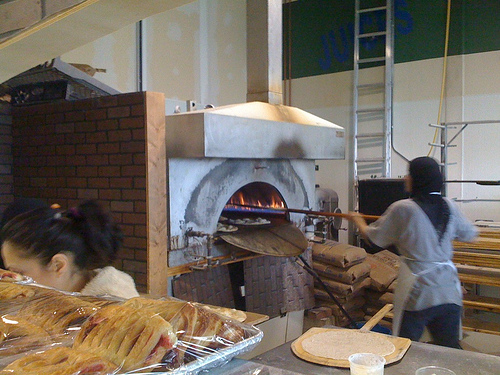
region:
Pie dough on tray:
[297, 321, 409, 368]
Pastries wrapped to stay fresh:
[4, 275, 260, 372]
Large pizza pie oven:
[153, 92, 339, 282]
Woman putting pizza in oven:
[342, 151, 483, 343]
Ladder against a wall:
[345, 4, 400, 245]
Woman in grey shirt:
[342, 152, 489, 352]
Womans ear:
[46, 250, 78, 279]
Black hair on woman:
[402, 157, 463, 239]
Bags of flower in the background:
[315, 238, 390, 318]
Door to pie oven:
[220, 221, 317, 261]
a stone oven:
[119, 78, 418, 308]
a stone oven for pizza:
[137, 77, 428, 327]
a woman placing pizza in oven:
[189, 45, 496, 279]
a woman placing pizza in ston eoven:
[125, 67, 497, 352]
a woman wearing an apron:
[325, 135, 499, 310]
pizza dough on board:
[285, 298, 436, 373]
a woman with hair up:
[4, 167, 141, 299]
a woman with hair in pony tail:
[4, 186, 154, 310]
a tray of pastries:
[7, 227, 273, 372]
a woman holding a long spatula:
[224, 139, 499, 269]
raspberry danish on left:
[83, 305, 161, 374]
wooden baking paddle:
[312, 310, 390, 372]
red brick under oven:
[252, 257, 309, 308]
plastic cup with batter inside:
[347, 347, 382, 374]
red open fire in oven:
[231, 188, 291, 231]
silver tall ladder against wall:
[355, 72, 405, 136]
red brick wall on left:
[89, 110, 166, 192]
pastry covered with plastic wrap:
[10, 318, 83, 359]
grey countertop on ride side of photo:
[431, 346, 488, 372]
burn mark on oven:
[274, 96, 309, 158]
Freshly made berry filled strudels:
[0, 261, 267, 371]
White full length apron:
[385, 250, 471, 345]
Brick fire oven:
[165, 120, 330, 246]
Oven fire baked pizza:
[227, 210, 273, 227]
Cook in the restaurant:
[372, 140, 479, 330]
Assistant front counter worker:
[1, 195, 157, 313]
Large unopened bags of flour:
[313, 226, 408, 321]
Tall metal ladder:
[340, 1, 395, 252]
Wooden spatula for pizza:
[281, 281, 422, 371]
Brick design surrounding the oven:
[12, 106, 154, 233]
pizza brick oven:
[187, 130, 330, 304]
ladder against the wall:
[342, 42, 414, 220]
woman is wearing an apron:
[370, 202, 498, 358]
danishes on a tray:
[82, 303, 240, 358]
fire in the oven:
[231, 192, 292, 209]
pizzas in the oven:
[220, 210, 298, 244]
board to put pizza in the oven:
[285, 276, 383, 373]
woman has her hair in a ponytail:
[31, 191, 174, 292]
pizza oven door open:
[247, 218, 343, 275]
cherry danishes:
[87, 310, 190, 373]